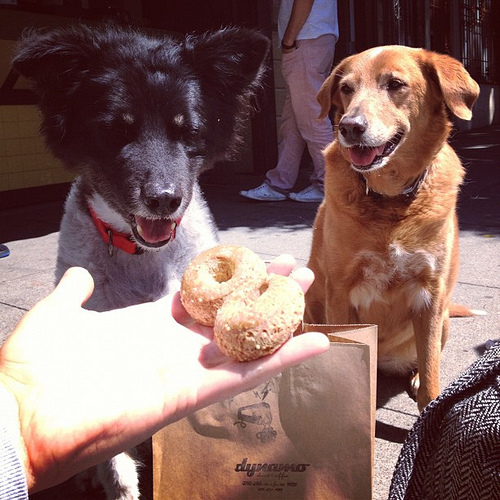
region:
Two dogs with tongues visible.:
[124, 142, 391, 247]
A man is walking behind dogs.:
[235, 0, 355, 205]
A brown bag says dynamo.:
[150, 322, 381, 497]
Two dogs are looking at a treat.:
[1, 22, 487, 399]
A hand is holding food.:
[0, 244, 329, 480]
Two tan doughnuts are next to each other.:
[178, 247, 303, 362]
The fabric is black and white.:
[385, 337, 495, 497]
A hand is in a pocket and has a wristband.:
[281, 34, 300, 78]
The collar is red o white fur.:
[76, 188, 142, 254]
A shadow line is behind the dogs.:
[5, 217, 497, 261]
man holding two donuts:
[167, 237, 327, 367]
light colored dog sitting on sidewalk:
[285, 35, 477, 425]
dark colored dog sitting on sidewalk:
[5, 11, 240, 288]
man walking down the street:
[266, 0, 338, 225]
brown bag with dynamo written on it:
[152, 307, 363, 493]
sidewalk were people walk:
[455, 155, 492, 370]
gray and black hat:
[386, 340, 493, 495]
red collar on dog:
[70, 210, 140, 255]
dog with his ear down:
[420, 47, 480, 113]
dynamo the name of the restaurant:
[225, 458, 355, 478]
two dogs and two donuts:
[19, 33, 454, 330]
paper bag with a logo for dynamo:
[227, 389, 318, 490]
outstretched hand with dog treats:
[22, 246, 318, 413]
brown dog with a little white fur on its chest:
[311, 48, 441, 401]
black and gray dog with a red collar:
[13, 27, 265, 281]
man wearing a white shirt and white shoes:
[242, 3, 339, 206]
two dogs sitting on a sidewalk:
[28, 24, 458, 407]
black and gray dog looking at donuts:
[12, 28, 271, 338]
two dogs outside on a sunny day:
[12, 20, 478, 401]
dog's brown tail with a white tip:
[443, 297, 490, 318]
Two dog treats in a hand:
[8, 240, 331, 475]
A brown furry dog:
[299, 39, 489, 407]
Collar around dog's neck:
[72, 186, 147, 263]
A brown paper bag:
[145, 316, 380, 497]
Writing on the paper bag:
[226, 382, 314, 494]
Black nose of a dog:
[139, 169, 184, 223]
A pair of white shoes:
[235, 171, 329, 209]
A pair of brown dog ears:
[305, 36, 483, 128]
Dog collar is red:
[69, 186, 150, 266]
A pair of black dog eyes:
[332, 69, 414, 101]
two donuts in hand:
[174, 243, 306, 350]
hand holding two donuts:
[1, 239, 336, 459]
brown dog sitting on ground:
[310, 46, 482, 404]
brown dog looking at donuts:
[309, 49, 481, 399]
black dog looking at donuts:
[13, 14, 279, 250]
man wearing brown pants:
[268, 45, 332, 183]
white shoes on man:
[236, 180, 289, 200]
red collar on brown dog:
[355, 189, 417, 211]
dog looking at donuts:
[22, 23, 272, 250]